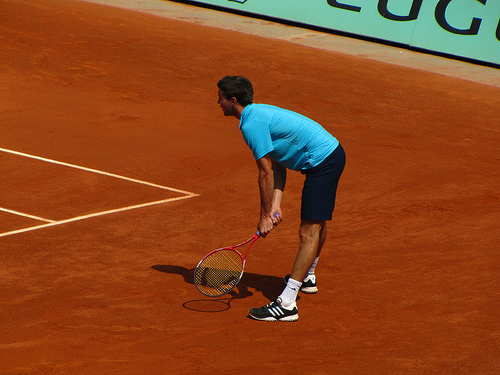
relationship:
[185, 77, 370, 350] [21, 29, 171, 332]
man on tennis court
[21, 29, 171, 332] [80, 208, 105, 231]
tennis court has lines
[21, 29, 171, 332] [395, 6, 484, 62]
tennis court has advertisement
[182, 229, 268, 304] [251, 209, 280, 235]
tennis racket in hand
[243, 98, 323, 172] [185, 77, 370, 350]
shirt on man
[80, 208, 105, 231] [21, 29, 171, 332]
lines on tennis court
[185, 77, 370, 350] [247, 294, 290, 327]
man has shoe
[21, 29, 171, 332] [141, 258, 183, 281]
tennis court has shadow